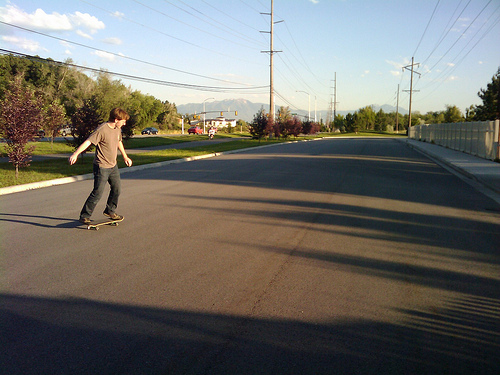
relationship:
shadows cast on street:
[2, 199, 63, 241] [0, 136, 499, 375]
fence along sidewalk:
[407, 120, 500, 161] [400, 136, 499, 207]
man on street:
[67, 107, 135, 222] [0, 138, 499, 375]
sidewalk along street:
[400, 136, 499, 207] [0, 138, 499, 375]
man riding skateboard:
[67, 107, 135, 222] [76, 212, 127, 232]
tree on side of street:
[2, 72, 45, 173] [0, 138, 499, 375]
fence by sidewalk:
[407, 120, 500, 161] [400, 136, 499, 207]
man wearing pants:
[67, 107, 135, 222] [77, 163, 125, 220]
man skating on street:
[67, 107, 135, 222] [0, 138, 499, 375]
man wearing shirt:
[67, 107, 135, 222] [90, 123, 123, 170]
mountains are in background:
[174, 97, 419, 125] [7, 0, 497, 117]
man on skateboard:
[67, 107, 135, 222] [76, 212, 127, 232]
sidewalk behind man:
[4, 132, 324, 194] [67, 107, 135, 222]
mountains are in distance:
[174, 97, 419, 125] [7, 0, 497, 117]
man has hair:
[67, 107, 135, 222] [108, 106, 132, 126]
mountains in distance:
[174, 97, 419, 125] [7, 0, 497, 117]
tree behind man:
[2, 72, 45, 173] [67, 107, 135, 222]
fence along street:
[407, 120, 500, 161] [0, 138, 499, 375]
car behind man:
[187, 124, 205, 137] [67, 107, 135, 222]